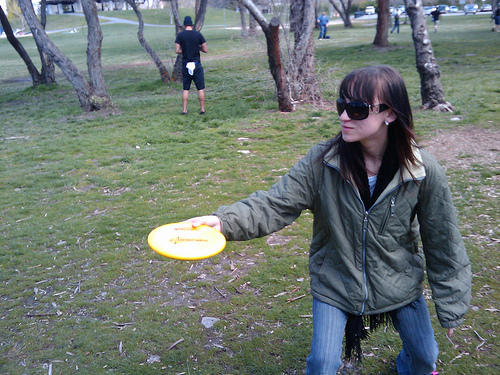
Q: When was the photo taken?
A: Daytime.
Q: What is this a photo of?
A: Woman throwing frisbee.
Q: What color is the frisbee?
A: Yellow.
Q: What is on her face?
A: Sunglasses.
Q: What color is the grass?
A: Green.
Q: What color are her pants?
A: Blue.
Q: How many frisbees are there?
A: One.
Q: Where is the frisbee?
A: In her hand.